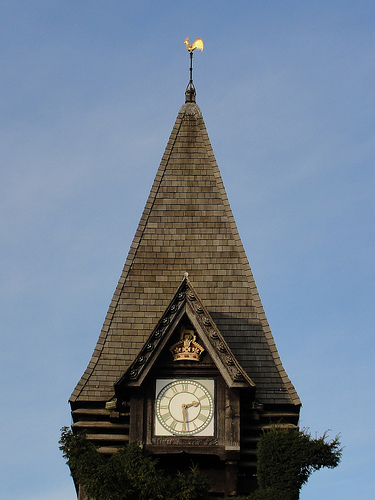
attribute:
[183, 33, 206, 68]
weather vane — gold